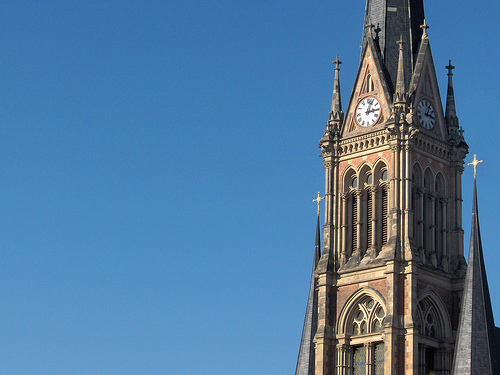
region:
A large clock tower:
[291, 0, 492, 369]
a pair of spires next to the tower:
[284, 148, 499, 369]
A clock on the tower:
[346, 90, 384, 134]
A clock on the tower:
[414, 97, 443, 134]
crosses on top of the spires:
[288, 118, 490, 213]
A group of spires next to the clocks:
[307, 13, 480, 100]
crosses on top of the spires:
[317, 17, 465, 72]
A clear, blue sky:
[2, 3, 498, 369]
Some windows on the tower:
[342, 338, 392, 373]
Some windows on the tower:
[420, 340, 443, 373]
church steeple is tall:
[314, 1, 454, 367]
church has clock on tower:
[351, 88, 380, 141]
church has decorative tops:
[314, 25, 456, 95]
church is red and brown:
[301, 53, 448, 371]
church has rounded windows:
[332, 285, 404, 374]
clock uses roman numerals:
[339, 92, 391, 141]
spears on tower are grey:
[442, 163, 499, 373]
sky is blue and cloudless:
[14, 47, 131, 259]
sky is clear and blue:
[10, 3, 186, 271]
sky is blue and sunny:
[32, 24, 196, 260]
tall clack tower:
[291, 0, 498, 374]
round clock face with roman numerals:
[352, 94, 381, 128]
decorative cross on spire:
[465, 152, 484, 179]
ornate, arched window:
[336, 292, 387, 373]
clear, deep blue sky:
[1, 0, 497, 373]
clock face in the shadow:
[413, 95, 441, 130]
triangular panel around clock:
[333, 34, 391, 141]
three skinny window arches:
[339, 159, 393, 255]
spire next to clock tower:
[450, 151, 498, 373]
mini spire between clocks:
[391, 32, 408, 104]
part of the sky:
[226, 120, 235, 130]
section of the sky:
[97, 253, 121, 278]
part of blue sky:
[196, 269, 231, 313]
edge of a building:
[396, 277, 404, 328]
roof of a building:
[475, 253, 478, 266]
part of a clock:
[422, 110, 437, 122]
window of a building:
[361, 323, 374, 338]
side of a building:
[320, 264, 332, 318]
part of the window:
[365, 355, 377, 362]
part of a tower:
[393, 70, 402, 92]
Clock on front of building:
[348, 93, 387, 133]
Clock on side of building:
[411, 94, 441, 138]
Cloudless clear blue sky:
[70, 130, 214, 236]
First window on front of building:
[343, 166, 357, 261]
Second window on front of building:
[358, 158, 373, 263]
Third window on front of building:
[374, 157, 392, 257]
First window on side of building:
[411, 158, 426, 253]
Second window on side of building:
[421, 162, 436, 252]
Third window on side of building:
[435, 168, 448, 268]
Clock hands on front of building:
[362, 96, 382, 116]